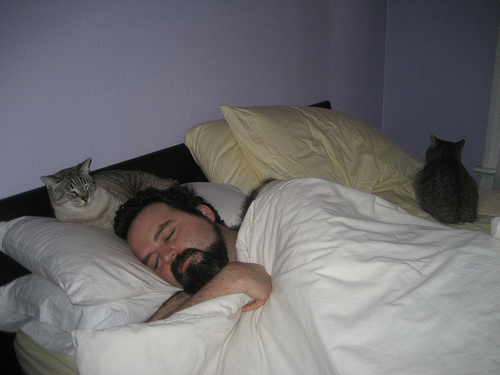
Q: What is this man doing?
A: Sleeping.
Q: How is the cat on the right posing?
A: Sitting.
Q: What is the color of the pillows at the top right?
A: Yellow.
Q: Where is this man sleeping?
A: His bed.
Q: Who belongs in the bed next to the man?
A: His wife.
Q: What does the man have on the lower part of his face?
A: A beard.